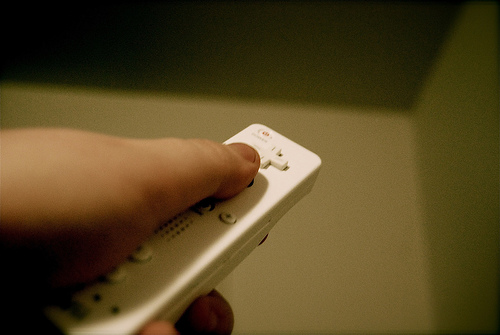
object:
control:
[46, 122, 322, 335]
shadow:
[1, 214, 127, 335]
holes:
[154, 214, 194, 242]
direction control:
[259, 145, 289, 170]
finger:
[135, 136, 261, 230]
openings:
[153, 215, 194, 242]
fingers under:
[137, 282, 242, 333]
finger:
[140, 320, 175, 335]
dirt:
[253, 151, 256, 162]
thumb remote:
[218, 122, 321, 191]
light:
[92, 293, 120, 316]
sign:
[258, 129, 272, 139]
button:
[260, 130, 273, 139]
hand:
[0, 126, 260, 335]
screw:
[225, 214, 231, 217]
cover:
[52, 119, 304, 316]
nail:
[227, 143, 256, 163]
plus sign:
[226, 214, 231, 218]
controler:
[44, 122, 321, 335]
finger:
[172, 289, 235, 335]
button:
[259, 145, 288, 170]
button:
[221, 211, 237, 225]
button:
[131, 243, 155, 263]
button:
[104, 264, 127, 283]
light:
[287, 105, 433, 335]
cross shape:
[259, 145, 289, 171]